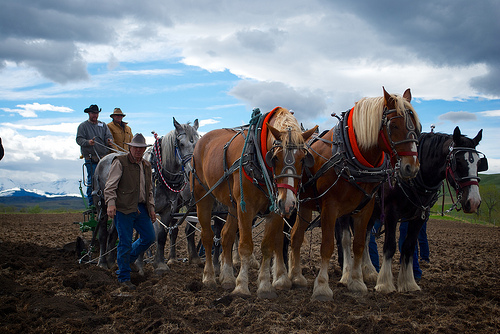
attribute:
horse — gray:
[150, 116, 200, 274]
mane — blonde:
[349, 95, 421, 148]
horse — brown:
[189, 108, 315, 298]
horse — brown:
[298, 90, 417, 295]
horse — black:
[375, 126, 487, 291]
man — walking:
[108, 136, 160, 289]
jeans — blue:
[112, 201, 158, 286]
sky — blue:
[2, 55, 499, 172]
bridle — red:
[331, 109, 387, 189]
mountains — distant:
[0, 184, 83, 208]